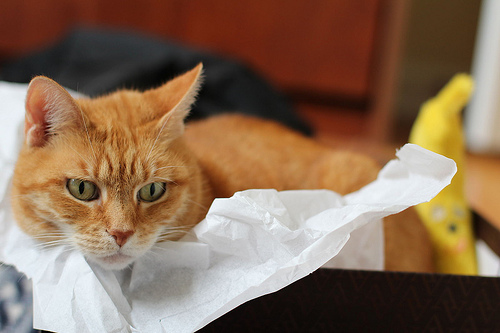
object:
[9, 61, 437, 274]
cat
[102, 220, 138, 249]
nose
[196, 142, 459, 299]
paper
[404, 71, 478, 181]
object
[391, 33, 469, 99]
door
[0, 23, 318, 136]
cloth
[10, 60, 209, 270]
head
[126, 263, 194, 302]
shadow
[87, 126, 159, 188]
stripe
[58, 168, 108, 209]
eye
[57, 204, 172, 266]
cheek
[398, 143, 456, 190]
edge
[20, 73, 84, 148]
ear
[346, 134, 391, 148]
floor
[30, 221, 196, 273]
whisker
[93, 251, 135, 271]
chin